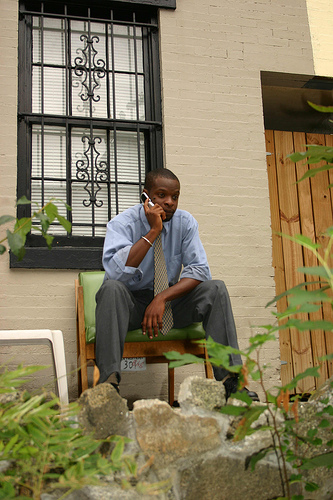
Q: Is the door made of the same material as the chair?
A: Yes, both the door and the chair are made of wood.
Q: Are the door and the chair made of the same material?
A: Yes, both the door and the chair are made of wood.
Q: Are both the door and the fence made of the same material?
A: Yes, both the door and the fence are made of wood.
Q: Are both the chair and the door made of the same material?
A: Yes, both the chair and the door are made of wood.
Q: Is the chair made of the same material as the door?
A: Yes, both the chair and the door are made of wood.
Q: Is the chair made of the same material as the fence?
A: Yes, both the chair and the fence are made of wood.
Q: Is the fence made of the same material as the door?
A: Yes, both the fence and the door are made of wood.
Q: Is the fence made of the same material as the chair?
A: Yes, both the fence and the chair are made of wood.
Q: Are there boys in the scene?
A: No, there are no boys.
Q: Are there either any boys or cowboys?
A: No, there are no boys or cowboys.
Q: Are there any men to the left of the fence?
A: Yes, there is a man to the left of the fence.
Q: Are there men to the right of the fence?
A: No, the man is to the left of the fence.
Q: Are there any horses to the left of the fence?
A: No, there is a man to the left of the fence.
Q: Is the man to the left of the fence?
A: Yes, the man is to the left of the fence.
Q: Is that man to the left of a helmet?
A: No, the man is to the left of the fence.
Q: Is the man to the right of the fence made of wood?
A: No, the man is to the left of the fence.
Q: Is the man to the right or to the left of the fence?
A: The man is to the left of the fence.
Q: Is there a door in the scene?
A: Yes, there is a door.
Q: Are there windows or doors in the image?
A: Yes, there is a door.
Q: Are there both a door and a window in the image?
A: Yes, there are both a door and a window.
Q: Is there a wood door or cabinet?
A: Yes, there is a wood door.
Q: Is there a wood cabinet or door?
A: Yes, there is a wood door.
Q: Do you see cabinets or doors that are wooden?
A: Yes, the door is wooden.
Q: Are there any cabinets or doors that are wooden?
A: Yes, the door is wooden.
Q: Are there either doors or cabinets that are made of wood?
A: Yes, the door is made of wood.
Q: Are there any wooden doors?
A: Yes, there is a wood door.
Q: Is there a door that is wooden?
A: Yes, there is a door that is wooden.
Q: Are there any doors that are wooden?
A: Yes, there is a door that is wooden.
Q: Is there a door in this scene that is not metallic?
A: Yes, there is a wooden door.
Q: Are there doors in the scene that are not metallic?
A: Yes, there is a wooden door.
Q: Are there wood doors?
A: Yes, there is a door that is made of wood.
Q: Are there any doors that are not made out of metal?
A: Yes, there is a door that is made of wood.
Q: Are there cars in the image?
A: No, there are no cars.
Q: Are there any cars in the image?
A: No, there are no cars.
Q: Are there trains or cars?
A: No, there are no cars or trains.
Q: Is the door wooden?
A: Yes, the door is wooden.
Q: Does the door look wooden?
A: Yes, the door is wooden.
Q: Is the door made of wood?
A: Yes, the door is made of wood.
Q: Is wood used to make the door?
A: Yes, the door is made of wood.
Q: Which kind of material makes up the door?
A: The door is made of wood.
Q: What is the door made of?
A: The door is made of wood.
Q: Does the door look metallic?
A: No, the door is wooden.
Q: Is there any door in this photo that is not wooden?
A: No, there is a door but it is wooden.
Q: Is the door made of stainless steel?
A: No, the door is made of wood.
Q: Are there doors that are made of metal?
A: No, there is a door but it is made of wood.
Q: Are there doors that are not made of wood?
A: No, there is a door but it is made of wood.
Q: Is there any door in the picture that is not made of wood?
A: No, there is a door but it is made of wood.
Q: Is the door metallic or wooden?
A: The door is wooden.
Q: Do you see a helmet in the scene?
A: No, there are no helmets.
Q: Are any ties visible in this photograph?
A: Yes, there is a tie.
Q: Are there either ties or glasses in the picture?
A: Yes, there is a tie.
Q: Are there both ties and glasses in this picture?
A: No, there is a tie but no glasses.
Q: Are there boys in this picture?
A: No, there are no boys.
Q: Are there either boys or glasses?
A: No, there are no boys or glasses.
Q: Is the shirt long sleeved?
A: Yes, the shirt is long sleeved.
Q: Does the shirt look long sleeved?
A: Yes, the shirt is long sleeved.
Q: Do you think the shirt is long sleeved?
A: Yes, the shirt is long sleeved.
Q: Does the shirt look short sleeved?
A: No, the shirt is long sleeved.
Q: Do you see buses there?
A: No, there are no buses.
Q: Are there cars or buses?
A: No, there are no buses or cars.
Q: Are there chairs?
A: Yes, there is a chair.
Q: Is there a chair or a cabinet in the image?
A: Yes, there is a chair.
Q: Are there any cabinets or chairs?
A: Yes, there is a chair.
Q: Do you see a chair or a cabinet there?
A: Yes, there is a chair.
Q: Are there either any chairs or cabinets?
A: Yes, there is a chair.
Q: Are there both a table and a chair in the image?
A: No, there is a chair but no tables.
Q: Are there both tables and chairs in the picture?
A: No, there is a chair but no tables.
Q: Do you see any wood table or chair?
A: Yes, there is a wood chair.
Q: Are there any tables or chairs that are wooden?
A: Yes, the chair is wooden.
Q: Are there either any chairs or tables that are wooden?
A: Yes, the chair is wooden.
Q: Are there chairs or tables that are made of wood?
A: Yes, the chair is made of wood.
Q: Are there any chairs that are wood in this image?
A: Yes, there is a wood chair.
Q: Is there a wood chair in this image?
A: Yes, there is a wood chair.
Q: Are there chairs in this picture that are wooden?
A: Yes, there is a chair that is wooden.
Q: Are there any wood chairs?
A: Yes, there is a chair that is made of wood.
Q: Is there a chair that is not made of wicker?
A: Yes, there is a chair that is made of wood.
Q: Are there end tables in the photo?
A: No, there are no end tables.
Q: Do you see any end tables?
A: No, there are no end tables.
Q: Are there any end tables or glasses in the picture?
A: No, there are no end tables or glasses.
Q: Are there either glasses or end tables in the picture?
A: No, there are no end tables or glasses.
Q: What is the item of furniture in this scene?
A: The piece of furniture is a chair.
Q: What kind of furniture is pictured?
A: The furniture is a chair.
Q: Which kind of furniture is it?
A: The piece of furniture is a chair.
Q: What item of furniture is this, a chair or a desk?
A: That is a chair.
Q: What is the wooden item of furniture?
A: The piece of furniture is a chair.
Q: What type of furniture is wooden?
A: The furniture is a chair.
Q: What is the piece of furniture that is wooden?
A: The piece of furniture is a chair.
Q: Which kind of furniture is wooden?
A: The furniture is a chair.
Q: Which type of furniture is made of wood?
A: The furniture is a chair.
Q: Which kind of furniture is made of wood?
A: The furniture is a chair.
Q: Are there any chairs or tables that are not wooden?
A: No, there is a chair but it is wooden.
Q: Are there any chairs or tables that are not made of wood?
A: No, there is a chair but it is made of wood.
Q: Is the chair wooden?
A: Yes, the chair is wooden.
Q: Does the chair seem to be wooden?
A: Yes, the chair is wooden.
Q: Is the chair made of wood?
A: Yes, the chair is made of wood.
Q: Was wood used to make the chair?
A: Yes, the chair is made of wood.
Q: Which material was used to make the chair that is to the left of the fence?
A: The chair is made of wood.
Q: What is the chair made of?
A: The chair is made of wood.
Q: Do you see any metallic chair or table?
A: No, there is a chair but it is wooden.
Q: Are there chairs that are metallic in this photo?
A: No, there is a chair but it is wooden.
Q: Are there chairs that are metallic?
A: No, there is a chair but it is wooden.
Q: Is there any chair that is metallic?
A: No, there is a chair but it is wooden.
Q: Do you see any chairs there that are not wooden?
A: No, there is a chair but it is wooden.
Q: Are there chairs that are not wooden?
A: No, there is a chair but it is wooden.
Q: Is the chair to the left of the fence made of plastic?
A: No, the chair is made of wood.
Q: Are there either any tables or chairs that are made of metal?
A: No, there is a chair but it is made of wood.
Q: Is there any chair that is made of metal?
A: No, there is a chair but it is made of wood.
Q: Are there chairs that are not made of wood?
A: No, there is a chair but it is made of wood.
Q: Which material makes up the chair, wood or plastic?
A: The chair is made of wood.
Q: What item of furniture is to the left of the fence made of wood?
A: The piece of furniture is a chair.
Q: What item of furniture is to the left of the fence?
A: The piece of furniture is a chair.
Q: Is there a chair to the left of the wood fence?
A: Yes, there is a chair to the left of the fence.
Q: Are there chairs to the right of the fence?
A: No, the chair is to the left of the fence.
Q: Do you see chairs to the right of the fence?
A: No, the chair is to the left of the fence.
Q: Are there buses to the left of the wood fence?
A: No, there is a chair to the left of the fence.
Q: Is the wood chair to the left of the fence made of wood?
A: Yes, the chair is to the left of the fence.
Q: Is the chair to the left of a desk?
A: No, the chair is to the left of the fence.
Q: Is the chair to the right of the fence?
A: No, the chair is to the left of the fence.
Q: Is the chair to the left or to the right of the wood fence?
A: The chair is to the left of the fence.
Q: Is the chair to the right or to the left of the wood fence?
A: The chair is to the left of the fence.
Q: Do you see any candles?
A: No, there are no candles.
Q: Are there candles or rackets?
A: No, there are no candles or rackets.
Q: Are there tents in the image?
A: No, there are no tents.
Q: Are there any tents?
A: No, there are no tents.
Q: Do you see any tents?
A: No, there are no tents.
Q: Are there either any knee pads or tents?
A: No, there are no tents or knee pads.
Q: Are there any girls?
A: No, there are no girls.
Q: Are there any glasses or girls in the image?
A: No, there are no girls or glasses.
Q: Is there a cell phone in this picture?
A: Yes, there is a cell phone.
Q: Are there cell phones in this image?
A: Yes, there is a cell phone.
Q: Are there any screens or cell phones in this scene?
A: Yes, there is a cell phone.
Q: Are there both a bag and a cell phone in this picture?
A: No, there is a cell phone but no bags.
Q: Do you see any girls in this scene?
A: No, there are no girls.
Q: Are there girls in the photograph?
A: No, there are no girls.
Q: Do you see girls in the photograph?
A: No, there are no girls.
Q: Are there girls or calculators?
A: No, there are no girls or calculators.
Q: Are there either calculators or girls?
A: No, there are no girls or calculators.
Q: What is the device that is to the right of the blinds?
A: The device is a cell phone.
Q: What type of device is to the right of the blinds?
A: The device is a cell phone.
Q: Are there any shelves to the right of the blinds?
A: No, there is a cell phone to the right of the blinds.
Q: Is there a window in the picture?
A: Yes, there is a window.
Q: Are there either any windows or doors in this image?
A: Yes, there is a window.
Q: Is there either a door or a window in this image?
A: Yes, there is a window.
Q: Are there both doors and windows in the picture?
A: Yes, there are both a window and a door.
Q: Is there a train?
A: No, there are no trains.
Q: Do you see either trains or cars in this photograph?
A: No, there are no trains or cars.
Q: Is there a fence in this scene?
A: Yes, there is a fence.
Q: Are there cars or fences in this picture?
A: Yes, there is a fence.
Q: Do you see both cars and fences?
A: No, there is a fence but no cars.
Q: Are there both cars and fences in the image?
A: No, there is a fence but no cars.